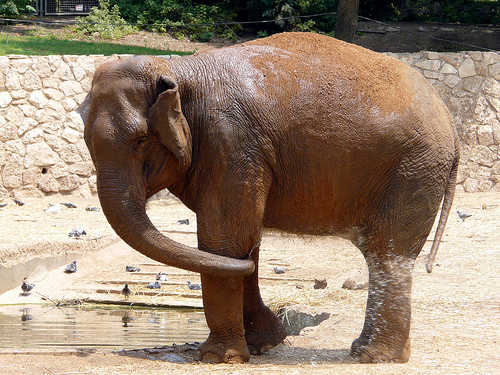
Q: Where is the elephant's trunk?
A: Around the leg.